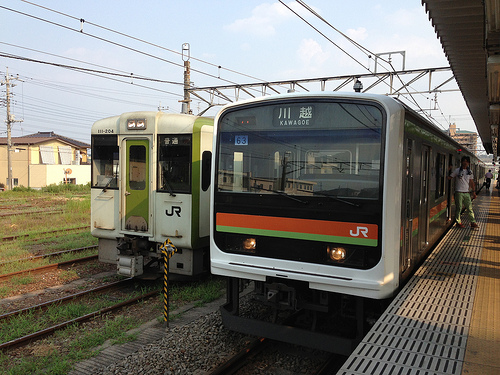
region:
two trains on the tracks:
[83, 96, 435, 296]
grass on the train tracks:
[25, 194, 125, 260]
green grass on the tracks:
[10, 188, 107, 316]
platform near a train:
[394, 240, 489, 368]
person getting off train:
[446, 151, 479, 241]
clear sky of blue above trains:
[40, 42, 232, 127]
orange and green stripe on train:
[215, 207, 395, 253]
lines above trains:
[22, 53, 392, 109]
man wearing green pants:
[450, 155, 466, 237]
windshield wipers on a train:
[226, 131, 384, 213]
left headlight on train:
[320, 236, 353, 269]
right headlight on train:
[236, 230, 262, 257]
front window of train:
[216, 127, 386, 215]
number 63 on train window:
[229, 132, 253, 152]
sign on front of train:
[266, 104, 322, 133]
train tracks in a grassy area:
[37, 275, 122, 338]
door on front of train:
[118, 132, 159, 241]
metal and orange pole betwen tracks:
[151, 231, 182, 336]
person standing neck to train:
[445, 161, 488, 238]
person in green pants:
[452, 189, 482, 232]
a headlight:
[328, 243, 360, 265]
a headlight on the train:
[243, 235, 260, 255]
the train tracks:
[29, 226, 76, 269]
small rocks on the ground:
[156, 339, 198, 363]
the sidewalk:
[464, 310, 496, 341]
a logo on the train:
[350, 222, 372, 239]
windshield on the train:
[221, 139, 373, 209]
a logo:
[165, 202, 186, 220]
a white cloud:
[292, 36, 327, 67]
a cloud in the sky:
[295, 44, 329, 68]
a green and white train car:
[85, 107, 205, 289]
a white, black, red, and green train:
[210, 83, 489, 303]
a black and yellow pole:
[152, 232, 177, 332]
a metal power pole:
[0, 65, 23, 187]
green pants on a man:
[453, 180, 481, 234]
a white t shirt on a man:
[453, 157, 481, 194]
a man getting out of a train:
[450, 142, 484, 237]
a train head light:
[328, 243, 350, 265]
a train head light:
[240, 233, 265, 253]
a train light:
[120, 115, 149, 127]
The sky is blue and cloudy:
[154, 2, 339, 97]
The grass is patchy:
[17, 248, 131, 373]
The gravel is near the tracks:
[131, 332, 236, 373]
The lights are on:
[231, 238, 368, 267]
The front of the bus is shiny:
[223, 99, 375, 254]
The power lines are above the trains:
[59, 14, 310, 119]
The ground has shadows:
[441, 180, 496, 274]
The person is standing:
[446, 147, 498, 235]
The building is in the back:
[3, 110, 121, 222]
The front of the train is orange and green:
[211, 208, 388, 256]